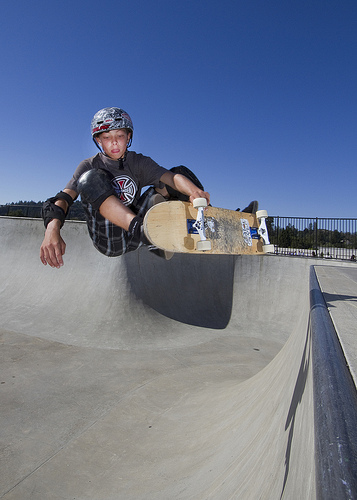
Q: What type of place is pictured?
A: It is a park.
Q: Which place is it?
A: It is a park.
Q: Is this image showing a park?
A: Yes, it is showing a park.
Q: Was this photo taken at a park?
A: Yes, it was taken in a park.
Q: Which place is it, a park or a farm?
A: It is a park.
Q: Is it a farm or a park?
A: It is a park.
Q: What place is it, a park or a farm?
A: It is a park.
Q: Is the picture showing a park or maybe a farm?
A: It is showing a park.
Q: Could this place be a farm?
A: No, it is a park.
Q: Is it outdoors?
A: Yes, it is outdoors.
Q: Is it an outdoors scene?
A: Yes, it is outdoors.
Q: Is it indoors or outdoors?
A: It is outdoors.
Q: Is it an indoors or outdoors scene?
A: It is outdoors.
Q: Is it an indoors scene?
A: No, it is outdoors.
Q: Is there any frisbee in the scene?
A: No, there are no frisbees.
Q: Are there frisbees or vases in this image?
A: No, there are no frisbees or vases.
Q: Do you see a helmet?
A: Yes, there is a helmet.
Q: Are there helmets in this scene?
A: Yes, there is a helmet.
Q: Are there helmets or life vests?
A: Yes, there is a helmet.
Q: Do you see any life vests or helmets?
A: Yes, there is a helmet.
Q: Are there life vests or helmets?
A: Yes, there is a helmet.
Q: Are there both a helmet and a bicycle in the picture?
A: No, there is a helmet but no bicycles.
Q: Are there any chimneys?
A: No, there are no chimneys.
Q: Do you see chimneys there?
A: No, there are no chimneys.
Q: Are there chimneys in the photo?
A: No, there are no chimneys.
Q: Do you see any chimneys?
A: No, there are no chimneys.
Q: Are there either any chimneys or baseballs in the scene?
A: No, there are no chimneys or baseballs.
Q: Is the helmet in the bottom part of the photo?
A: No, the helmet is in the top of the image.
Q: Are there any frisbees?
A: No, there are no frisbees.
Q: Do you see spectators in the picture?
A: No, there are no spectators.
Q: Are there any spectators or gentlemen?
A: No, there are no spectators or gentlemen.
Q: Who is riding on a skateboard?
A: The boy is riding on a skateboard.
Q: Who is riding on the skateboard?
A: The boy is riding on a skateboard.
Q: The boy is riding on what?
A: The boy is riding on a skateboard.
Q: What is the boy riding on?
A: The boy is riding on a skateboard.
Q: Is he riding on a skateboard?
A: Yes, the boy is riding on a skateboard.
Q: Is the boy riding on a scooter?
A: No, the boy is riding on a skateboard.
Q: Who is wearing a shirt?
A: The boy is wearing a shirt.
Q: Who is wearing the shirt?
A: The boy is wearing a shirt.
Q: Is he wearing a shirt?
A: Yes, the boy is wearing a shirt.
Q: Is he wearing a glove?
A: No, the boy is wearing a shirt.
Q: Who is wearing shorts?
A: The boy is wearing shorts.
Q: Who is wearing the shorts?
A: The boy is wearing shorts.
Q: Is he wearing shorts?
A: Yes, the boy is wearing shorts.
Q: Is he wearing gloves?
A: No, the boy is wearing shorts.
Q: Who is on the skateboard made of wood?
A: The boy is on the skateboard.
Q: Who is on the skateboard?
A: The boy is on the skateboard.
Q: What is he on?
A: The boy is on the skateboard.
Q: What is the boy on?
A: The boy is on the skateboard.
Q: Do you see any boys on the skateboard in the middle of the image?
A: Yes, there is a boy on the skateboard.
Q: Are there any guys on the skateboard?
A: No, there is a boy on the skateboard.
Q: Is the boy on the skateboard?
A: Yes, the boy is on the skateboard.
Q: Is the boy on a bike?
A: No, the boy is on the skateboard.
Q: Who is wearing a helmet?
A: The boy is wearing a helmet.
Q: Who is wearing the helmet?
A: The boy is wearing a helmet.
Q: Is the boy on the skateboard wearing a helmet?
A: Yes, the boy is wearing a helmet.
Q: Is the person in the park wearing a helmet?
A: Yes, the boy is wearing a helmet.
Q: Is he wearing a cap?
A: No, the boy is wearing a helmet.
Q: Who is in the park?
A: The boy is in the park.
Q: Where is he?
A: The boy is in the park.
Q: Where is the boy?
A: The boy is in the park.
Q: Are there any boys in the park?
A: Yes, there is a boy in the park.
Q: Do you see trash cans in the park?
A: No, there is a boy in the park.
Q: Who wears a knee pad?
A: The boy wears a knee pad.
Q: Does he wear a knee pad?
A: Yes, the boy wears a knee pad.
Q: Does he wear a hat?
A: No, the boy wears a knee pad.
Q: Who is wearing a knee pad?
A: The boy is wearing a knee pad.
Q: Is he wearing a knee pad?
A: Yes, the boy is wearing a knee pad.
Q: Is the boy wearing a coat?
A: No, the boy is wearing a knee pad.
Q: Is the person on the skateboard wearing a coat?
A: No, the boy is wearing a knee pad.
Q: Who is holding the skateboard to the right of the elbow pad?
A: The boy is holding the skateboard.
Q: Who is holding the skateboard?
A: The boy is holding the skateboard.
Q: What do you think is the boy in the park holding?
A: The boy is holding the skateboard.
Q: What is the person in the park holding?
A: The boy is holding the skateboard.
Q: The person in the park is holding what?
A: The boy is holding the skateboard.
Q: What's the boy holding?
A: The boy is holding the skateboard.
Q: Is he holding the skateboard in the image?
A: Yes, the boy is holding the skateboard.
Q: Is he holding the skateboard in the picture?
A: Yes, the boy is holding the skateboard.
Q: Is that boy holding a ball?
A: No, the boy is holding the skateboard.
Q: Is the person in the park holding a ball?
A: No, the boy is holding the skateboard.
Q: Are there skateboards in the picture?
A: Yes, there is a skateboard.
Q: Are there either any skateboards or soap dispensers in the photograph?
A: Yes, there is a skateboard.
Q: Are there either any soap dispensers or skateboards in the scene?
A: Yes, there is a skateboard.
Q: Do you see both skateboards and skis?
A: No, there is a skateboard but no skis.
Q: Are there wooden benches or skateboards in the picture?
A: Yes, there is a wood skateboard.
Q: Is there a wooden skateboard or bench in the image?
A: Yes, there is a wood skateboard.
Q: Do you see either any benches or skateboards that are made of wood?
A: Yes, the skateboard is made of wood.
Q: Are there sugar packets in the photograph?
A: No, there are no sugar packets.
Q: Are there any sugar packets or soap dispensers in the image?
A: No, there are no sugar packets or soap dispensers.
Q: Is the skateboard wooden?
A: Yes, the skateboard is wooden.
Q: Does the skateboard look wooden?
A: Yes, the skateboard is wooden.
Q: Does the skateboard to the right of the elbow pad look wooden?
A: Yes, the skateboard is wooden.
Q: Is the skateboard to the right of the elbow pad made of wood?
A: Yes, the skateboard is made of wood.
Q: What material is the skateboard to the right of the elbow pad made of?
A: The skateboard is made of wood.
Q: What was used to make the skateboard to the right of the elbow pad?
A: The skateboard is made of wood.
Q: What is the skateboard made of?
A: The skateboard is made of wood.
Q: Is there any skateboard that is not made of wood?
A: No, there is a skateboard but it is made of wood.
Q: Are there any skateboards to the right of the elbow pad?
A: Yes, there is a skateboard to the right of the elbow pad.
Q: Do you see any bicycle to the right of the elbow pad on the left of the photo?
A: No, there is a skateboard to the right of the elbow pad.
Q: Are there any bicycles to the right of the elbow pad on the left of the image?
A: No, there is a skateboard to the right of the elbow pad.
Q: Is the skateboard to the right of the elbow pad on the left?
A: Yes, the skateboard is to the right of the elbow pad.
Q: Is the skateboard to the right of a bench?
A: No, the skateboard is to the right of the elbow pad.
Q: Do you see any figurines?
A: No, there are no figurines.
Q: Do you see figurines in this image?
A: No, there are no figurines.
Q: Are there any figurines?
A: No, there are no figurines.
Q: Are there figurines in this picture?
A: No, there are no figurines.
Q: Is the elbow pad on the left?
A: Yes, the elbow pad is on the left of the image.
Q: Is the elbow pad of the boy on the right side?
A: No, the elbow pad is on the left of the image.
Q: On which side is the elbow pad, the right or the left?
A: The elbow pad is on the left of the image.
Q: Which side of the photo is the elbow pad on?
A: The elbow pad is on the left of the image.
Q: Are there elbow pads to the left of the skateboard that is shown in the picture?
A: Yes, there is an elbow pad to the left of the skateboard.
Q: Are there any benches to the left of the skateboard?
A: No, there is an elbow pad to the left of the skateboard.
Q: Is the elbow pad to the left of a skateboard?
A: Yes, the elbow pad is to the left of a skateboard.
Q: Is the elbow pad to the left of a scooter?
A: No, the elbow pad is to the left of a skateboard.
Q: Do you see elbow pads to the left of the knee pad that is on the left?
A: Yes, there is an elbow pad to the left of the knee pad.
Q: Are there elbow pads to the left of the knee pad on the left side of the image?
A: Yes, there is an elbow pad to the left of the knee pad.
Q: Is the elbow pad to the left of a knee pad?
A: Yes, the elbow pad is to the left of a knee pad.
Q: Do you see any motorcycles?
A: No, there are no motorcycles.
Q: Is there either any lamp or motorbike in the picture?
A: No, there are no motorcycles or lamps.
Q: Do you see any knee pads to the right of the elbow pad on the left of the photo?
A: Yes, there is a knee pad to the right of the elbow pad.